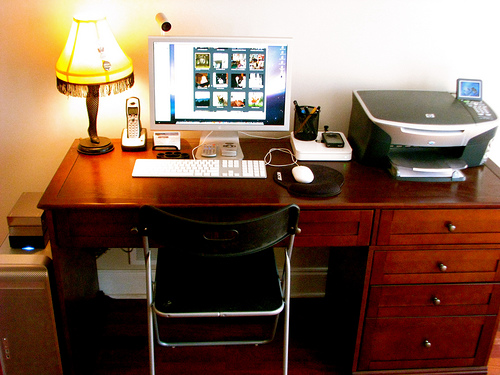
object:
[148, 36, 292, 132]
monitor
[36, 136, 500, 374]
desk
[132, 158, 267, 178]
keyboard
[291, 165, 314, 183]
mouse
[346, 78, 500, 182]
printer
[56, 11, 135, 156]
lamp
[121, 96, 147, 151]
phone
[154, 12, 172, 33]
camera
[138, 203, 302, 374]
chair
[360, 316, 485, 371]
drawer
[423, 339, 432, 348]
knob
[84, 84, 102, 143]
leg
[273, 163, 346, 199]
mouse pad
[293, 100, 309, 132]
pen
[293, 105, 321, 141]
pencil holder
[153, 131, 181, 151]
card holder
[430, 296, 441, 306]
knob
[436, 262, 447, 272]
knob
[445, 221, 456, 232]
knob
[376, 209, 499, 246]
drawer